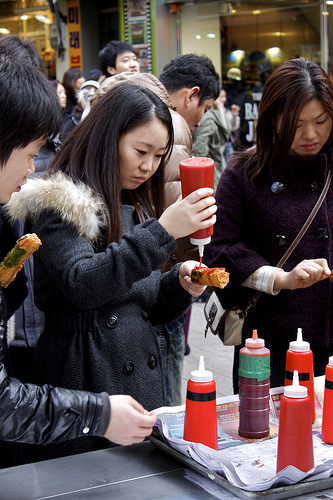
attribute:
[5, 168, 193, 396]
coat — gray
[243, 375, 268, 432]
bottle — bright red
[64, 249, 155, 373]
coat — purple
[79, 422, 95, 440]
buttons — large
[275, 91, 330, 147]
girl — asian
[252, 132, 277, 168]
hair — black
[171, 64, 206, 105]
boy — asian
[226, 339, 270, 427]
bottle — plastic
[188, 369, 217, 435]
bottle — plastic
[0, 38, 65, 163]
hair — black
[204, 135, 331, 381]
coat — purple